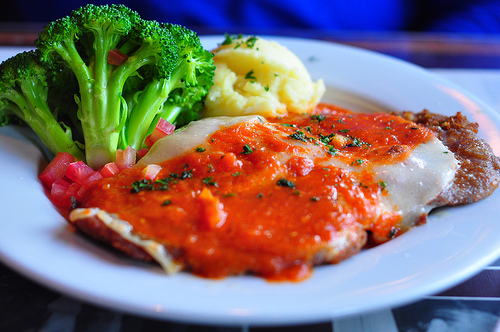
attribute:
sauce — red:
[70, 105, 422, 255]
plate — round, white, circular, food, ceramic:
[15, 26, 485, 320]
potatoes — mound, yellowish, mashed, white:
[208, 31, 327, 111]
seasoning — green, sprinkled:
[131, 38, 365, 198]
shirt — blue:
[173, 3, 470, 17]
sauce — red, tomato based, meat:
[70, 106, 475, 263]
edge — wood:
[5, 32, 473, 64]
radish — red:
[32, 144, 168, 200]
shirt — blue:
[26, 0, 498, 67]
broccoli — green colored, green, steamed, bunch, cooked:
[2, 7, 218, 167]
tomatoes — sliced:
[30, 145, 173, 201]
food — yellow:
[201, 25, 330, 115]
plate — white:
[2, 20, 498, 330]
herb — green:
[124, 158, 225, 199]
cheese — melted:
[130, 105, 468, 219]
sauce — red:
[64, 98, 436, 292]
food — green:
[0, 0, 220, 171]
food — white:
[197, 33, 330, 123]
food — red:
[34, 98, 438, 287]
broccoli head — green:
[0, 3, 217, 172]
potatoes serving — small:
[205, 35, 332, 122]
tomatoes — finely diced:
[36, 110, 176, 218]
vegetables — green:
[1, 3, 218, 171]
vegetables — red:
[37, 118, 176, 220]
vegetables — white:
[201, 36, 327, 120]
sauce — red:
[75, 101, 441, 282]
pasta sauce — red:
[80, 100, 439, 283]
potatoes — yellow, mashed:
[203, 33, 327, 123]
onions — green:
[216, 32, 280, 92]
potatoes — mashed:
[197, 27, 327, 117]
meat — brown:
[66, 109, 496, 276]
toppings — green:
[64, 112, 423, 212]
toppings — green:
[215, 30, 283, 90]